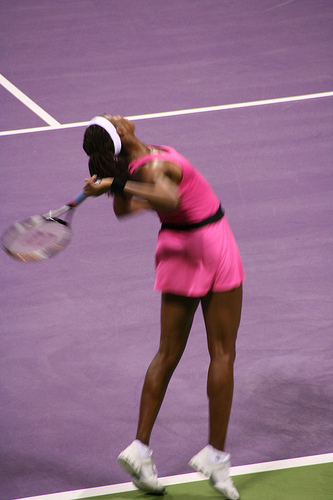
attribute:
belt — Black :
[158, 206, 227, 233]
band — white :
[84, 116, 121, 161]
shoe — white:
[104, 438, 259, 498]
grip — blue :
[67, 180, 102, 204]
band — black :
[111, 176, 129, 190]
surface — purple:
[0, 1, 331, 497]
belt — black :
[158, 205, 226, 238]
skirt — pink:
[151, 226, 253, 292]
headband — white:
[95, 161, 116, 219]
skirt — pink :
[123, 142, 248, 314]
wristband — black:
[108, 174, 129, 194]